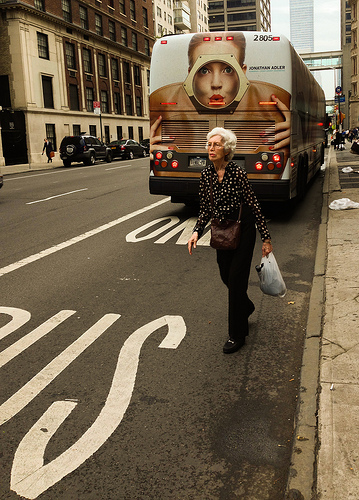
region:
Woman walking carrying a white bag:
[187, 125, 290, 358]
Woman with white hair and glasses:
[203, 124, 236, 162]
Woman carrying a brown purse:
[205, 207, 239, 245]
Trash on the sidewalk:
[326, 161, 357, 217]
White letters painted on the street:
[4, 293, 183, 494]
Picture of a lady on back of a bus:
[146, 36, 294, 124]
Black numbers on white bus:
[251, 30, 273, 40]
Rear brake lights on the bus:
[148, 147, 281, 172]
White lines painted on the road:
[0, 169, 123, 272]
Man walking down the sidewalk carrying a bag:
[38, 134, 53, 163]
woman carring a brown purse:
[189, 178, 246, 258]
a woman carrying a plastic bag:
[248, 228, 291, 319]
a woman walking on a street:
[199, 111, 260, 336]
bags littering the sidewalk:
[330, 156, 356, 240]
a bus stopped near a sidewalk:
[168, 25, 355, 143]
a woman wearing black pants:
[225, 244, 251, 354]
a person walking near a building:
[29, 136, 57, 168]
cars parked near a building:
[51, 131, 152, 167]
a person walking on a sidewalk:
[34, 137, 71, 180]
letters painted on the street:
[4, 309, 181, 438]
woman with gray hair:
[196, 123, 237, 164]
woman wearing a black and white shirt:
[189, 161, 247, 217]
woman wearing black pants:
[208, 233, 259, 324]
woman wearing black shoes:
[222, 328, 248, 353]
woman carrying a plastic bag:
[257, 237, 290, 305]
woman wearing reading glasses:
[202, 138, 221, 154]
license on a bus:
[185, 152, 206, 169]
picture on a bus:
[191, 46, 257, 112]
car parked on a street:
[56, 131, 109, 165]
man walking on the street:
[38, 133, 55, 164]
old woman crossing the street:
[174, 114, 299, 347]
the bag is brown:
[189, 199, 264, 268]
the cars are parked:
[51, 114, 148, 177]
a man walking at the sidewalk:
[34, 131, 55, 165]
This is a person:
[188, 119, 291, 362]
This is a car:
[56, 129, 109, 167]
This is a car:
[107, 133, 149, 160]